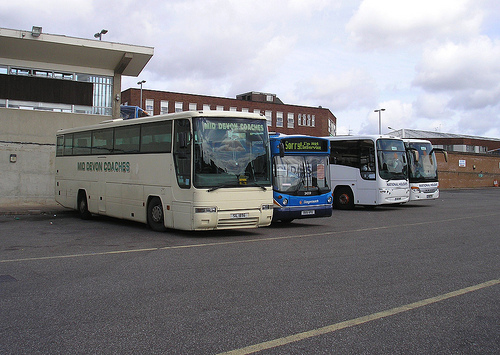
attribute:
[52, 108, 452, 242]
buses — parked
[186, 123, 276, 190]
window — large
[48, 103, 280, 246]
bus — white, one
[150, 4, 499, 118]
sky — blue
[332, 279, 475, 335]
line — white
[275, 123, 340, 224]
bus — blue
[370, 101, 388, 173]
street lamp — tall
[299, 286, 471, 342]
line — white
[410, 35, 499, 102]
clouds — white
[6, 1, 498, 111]
sky — blue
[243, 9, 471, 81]
clouds — white, some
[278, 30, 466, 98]
sky — one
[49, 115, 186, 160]
windows — some, bus, vehicular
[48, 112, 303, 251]
bus — white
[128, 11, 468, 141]
sky — cloudy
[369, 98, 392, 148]
light — street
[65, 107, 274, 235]
bus — white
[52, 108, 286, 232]
bus — white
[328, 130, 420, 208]
bus — white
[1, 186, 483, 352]
street — gray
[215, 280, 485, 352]
line — white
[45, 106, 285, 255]
bus — white